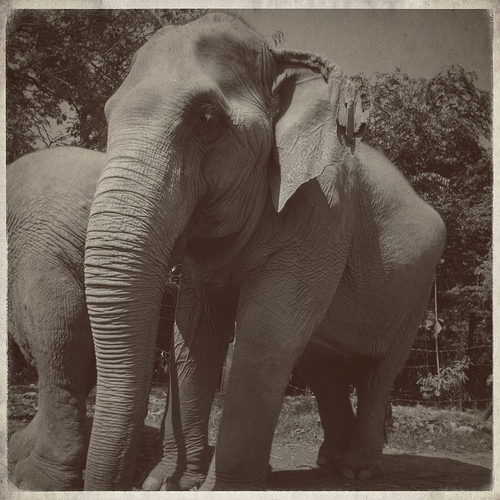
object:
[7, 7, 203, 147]
tree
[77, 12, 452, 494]
elephant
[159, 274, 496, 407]
fence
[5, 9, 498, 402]
trees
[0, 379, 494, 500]
ground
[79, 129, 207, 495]
trunk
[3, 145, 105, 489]
elephant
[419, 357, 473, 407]
leaves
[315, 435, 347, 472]
foot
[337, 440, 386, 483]
foot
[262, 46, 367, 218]
ear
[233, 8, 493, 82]
sky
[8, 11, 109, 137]
corner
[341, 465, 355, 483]
toe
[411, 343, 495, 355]
wire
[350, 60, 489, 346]
tree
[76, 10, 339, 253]
head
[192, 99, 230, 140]
eye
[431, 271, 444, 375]
pole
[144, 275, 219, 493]
leg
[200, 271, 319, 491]
leg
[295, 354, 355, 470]
leg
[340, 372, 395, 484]
leg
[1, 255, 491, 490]
park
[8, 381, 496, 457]
vegetation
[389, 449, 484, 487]
part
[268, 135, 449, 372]
body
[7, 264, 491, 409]
area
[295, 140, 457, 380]
belly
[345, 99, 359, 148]
ring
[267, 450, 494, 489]
shadow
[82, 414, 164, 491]
shadow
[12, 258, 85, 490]
leg